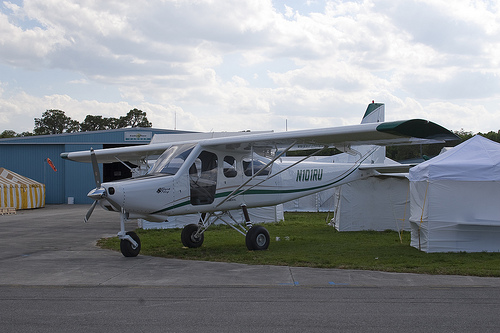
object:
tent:
[409, 133, 499, 254]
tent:
[335, 178, 410, 233]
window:
[142, 143, 196, 180]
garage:
[0, 125, 209, 211]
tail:
[341, 158, 417, 180]